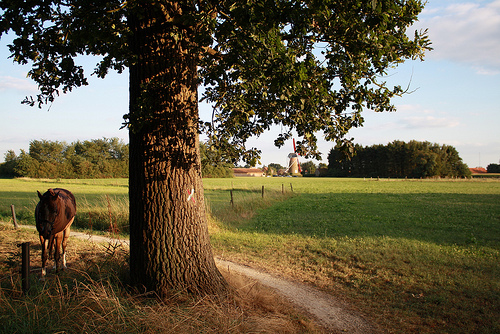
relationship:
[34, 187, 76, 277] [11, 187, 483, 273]
animal in shade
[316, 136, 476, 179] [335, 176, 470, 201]
trees behind grass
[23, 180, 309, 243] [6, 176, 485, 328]
fence in grass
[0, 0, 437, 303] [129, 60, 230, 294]
tree has trunk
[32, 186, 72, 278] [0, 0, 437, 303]
animal under tree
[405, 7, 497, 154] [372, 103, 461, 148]
sky has clouds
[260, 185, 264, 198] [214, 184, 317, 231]
stick in ground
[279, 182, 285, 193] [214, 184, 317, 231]
stick in ground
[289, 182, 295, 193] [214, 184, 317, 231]
stick in ground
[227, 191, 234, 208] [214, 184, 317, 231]
stick in ground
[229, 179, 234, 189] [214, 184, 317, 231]
stick in ground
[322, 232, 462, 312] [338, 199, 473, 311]
hay in ground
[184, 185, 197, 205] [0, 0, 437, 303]
white line on tree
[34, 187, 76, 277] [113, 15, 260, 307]
animal near tree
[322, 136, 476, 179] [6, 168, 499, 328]
trees in field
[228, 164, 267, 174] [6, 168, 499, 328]
house in field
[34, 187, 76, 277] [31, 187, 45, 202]
animal with perked up ear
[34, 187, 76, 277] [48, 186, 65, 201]
animal with perked up ear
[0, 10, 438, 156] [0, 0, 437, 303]
leaves on a tree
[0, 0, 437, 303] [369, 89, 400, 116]
tree with leaves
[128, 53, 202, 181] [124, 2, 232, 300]
shadow on trunk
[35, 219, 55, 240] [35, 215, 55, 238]
horse mouth on a horse mouth